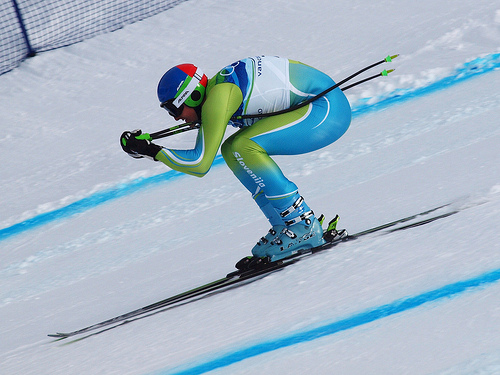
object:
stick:
[385, 53, 392, 63]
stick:
[380, 69, 389, 76]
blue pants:
[219, 90, 351, 199]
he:
[118, 54, 407, 268]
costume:
[142, 55, 354, 263]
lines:
[0, 54, 500, 373]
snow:
[189, 1, 499, 44]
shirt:
[197, 54, 353, 124]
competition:
[118, 54, 406, 274]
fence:
[2, 2, 190, 75]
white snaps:
[279, 195, 315, 227]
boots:
[251, 183, 326, 262]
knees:
[220, 139, 252, 160]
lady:
[119, 54, 351, 259]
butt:
[312, 92, 351, 149]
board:
[49, 194, 484, 342]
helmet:
[156, 63, 208, 119]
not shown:
[2, 0, 500, 374]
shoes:
[250, 203, 326, 262]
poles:
[134, 53, 402, 142]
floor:
[0, 114, 118, 194]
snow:
[0, 184, 215, 280]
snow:
[329, 242, 457, 309]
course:
[0, 0, 499, 375]